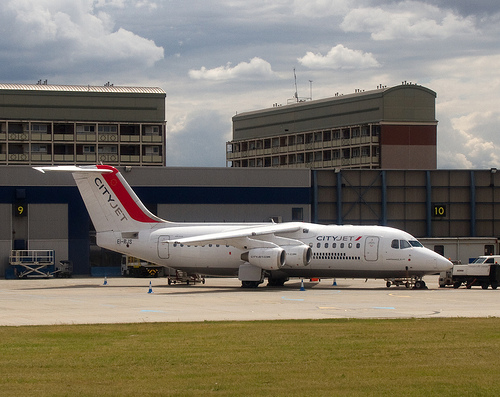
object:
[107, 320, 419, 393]
grass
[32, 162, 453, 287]
jet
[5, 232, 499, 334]
terminal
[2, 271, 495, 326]
tarmac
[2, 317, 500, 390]
field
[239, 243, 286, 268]
engine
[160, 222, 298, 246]
wing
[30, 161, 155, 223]
tail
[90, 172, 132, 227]
logo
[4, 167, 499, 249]
terminal building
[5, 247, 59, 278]
lift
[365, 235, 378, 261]
door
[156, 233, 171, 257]
exit door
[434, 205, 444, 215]
number 10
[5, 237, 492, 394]
airport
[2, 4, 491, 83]
sky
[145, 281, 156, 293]
cone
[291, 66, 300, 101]
antenna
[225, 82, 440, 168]
airport building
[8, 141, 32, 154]
windows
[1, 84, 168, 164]
building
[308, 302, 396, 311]
yellow and blue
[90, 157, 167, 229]
red stripe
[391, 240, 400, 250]
windshield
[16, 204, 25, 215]
gate 9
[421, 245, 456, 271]
nose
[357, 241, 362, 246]
windows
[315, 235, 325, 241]
writing